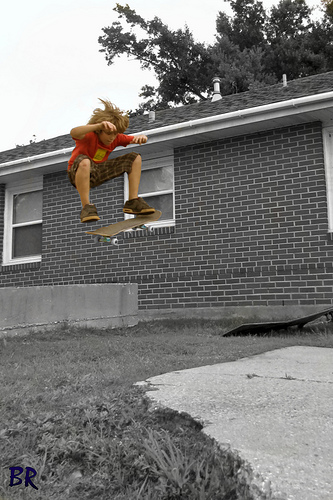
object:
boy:
[62, 94, 159, 227]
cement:
[124, 326, 330, 499]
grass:
[1, 305, 332, 499]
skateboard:
[84, 202, 164, 247]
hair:
[85, 100, 131, 137]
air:
[0, 0, 332, 146]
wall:
[0, 281, 146, 349]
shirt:
[62, 123, 133, 170]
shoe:
[120, 191, 158, 219]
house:
[0, 68, 332, 345]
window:
[0, 162, 58, 279]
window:
[114, 140, 185, 246]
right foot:
[75, 202, 102, 228]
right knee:
[73, 156, 95, 175]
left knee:
[120, 148, 147, 175]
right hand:
[98, 117, 120, 136]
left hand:
[131, 130, 150, 148]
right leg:
[67, 150, 101, 228]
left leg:
[98, 147, 157, 218]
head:
[84, 98, 134, 149]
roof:
[0, 66, 333, 186]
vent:
[278, 63, 299, 93]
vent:
[207, 68, 225, 109]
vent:
[136, 103, 163, 131]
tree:
[91, 1, 332, 121]